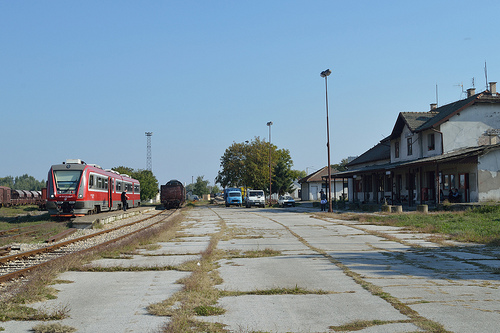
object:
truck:
[245, 190, 265, 208]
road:
[18, 204, 497, 333]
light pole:
[319, 68, 332, 211]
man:
[319, 190, 327, 211]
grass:
[468, 212, 499, 235]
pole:
[144, 132, 152, 173]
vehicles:
[278, 196, 296, 207]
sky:
[163, 59, 237, 115]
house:
[321, 82, 500, 210]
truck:
[224, 187, 242, 206]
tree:
[215, 135, 308, 203]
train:
[41, 159, 141, 217]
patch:
[172, 247, 226, 303]